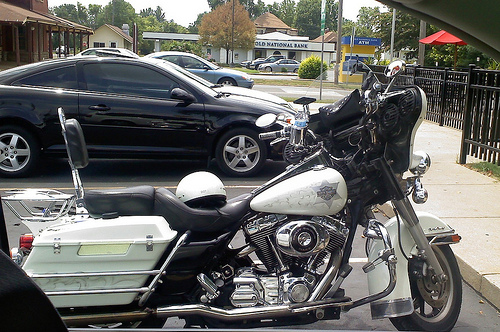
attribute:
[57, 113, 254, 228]
seat — black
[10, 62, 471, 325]
motorcycle — black, white, parked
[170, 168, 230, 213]
helmet — white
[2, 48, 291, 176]
car — black, parked, shiny, coupe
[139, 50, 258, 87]
car — silver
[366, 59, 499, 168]
fence — black, iron, metal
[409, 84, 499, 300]
sidewalk — concrete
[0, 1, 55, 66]
building — brick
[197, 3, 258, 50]
leaves — brown, green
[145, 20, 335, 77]
building — white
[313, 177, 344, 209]
star — gray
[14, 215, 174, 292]
case — white, storage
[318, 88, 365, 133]
case — black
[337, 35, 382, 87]
atm — yellow, blue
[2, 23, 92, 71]
porch — brown, wood, old, long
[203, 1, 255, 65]
tree — yellow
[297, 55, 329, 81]
bush — green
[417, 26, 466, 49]
umbrella — red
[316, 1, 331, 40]
sign — green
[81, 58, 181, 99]
window — closed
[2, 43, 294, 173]
cars — parked